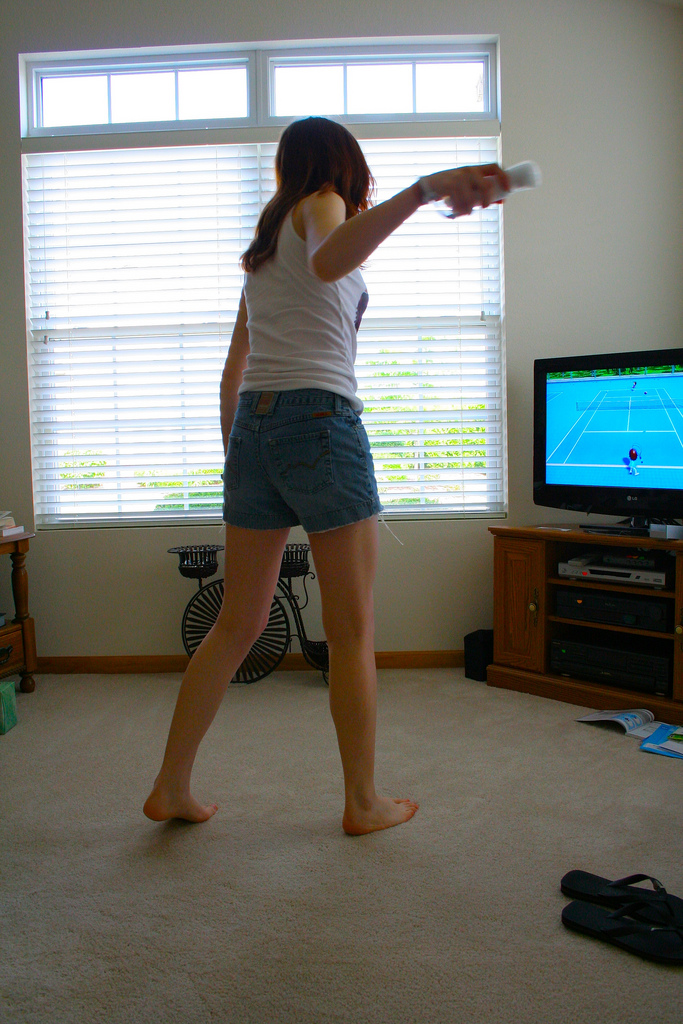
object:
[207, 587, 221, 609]
metal bar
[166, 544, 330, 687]
decoration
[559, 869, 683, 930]
flip flop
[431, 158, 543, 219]
remote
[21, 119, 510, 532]
blinds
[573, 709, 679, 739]
book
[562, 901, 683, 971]
flip flop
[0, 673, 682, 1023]
floor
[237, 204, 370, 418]
shirt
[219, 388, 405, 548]
shorts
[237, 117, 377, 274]
hair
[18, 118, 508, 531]
window blinds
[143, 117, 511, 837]
girl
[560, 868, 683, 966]
flip flop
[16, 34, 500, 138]
window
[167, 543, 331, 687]
furniture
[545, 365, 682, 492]
tv screen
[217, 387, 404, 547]
jean shorts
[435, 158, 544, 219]
game controller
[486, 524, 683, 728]
tv stand